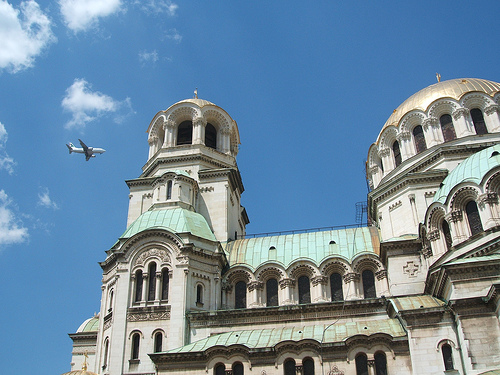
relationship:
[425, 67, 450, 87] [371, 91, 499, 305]
tip of building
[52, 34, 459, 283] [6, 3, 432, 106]
picture during day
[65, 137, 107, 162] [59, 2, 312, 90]
airplane in sky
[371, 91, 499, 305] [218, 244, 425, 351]
building has windows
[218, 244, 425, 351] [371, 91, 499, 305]
windows in building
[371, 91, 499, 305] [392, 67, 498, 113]
building with dome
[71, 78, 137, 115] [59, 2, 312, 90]
clouds in sky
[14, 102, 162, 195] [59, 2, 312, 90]
airplane in sky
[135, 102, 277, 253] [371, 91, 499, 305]
tower on building